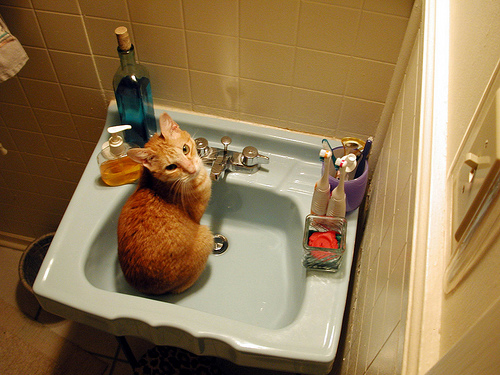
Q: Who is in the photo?
A: No one.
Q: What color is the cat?
A: Orange.